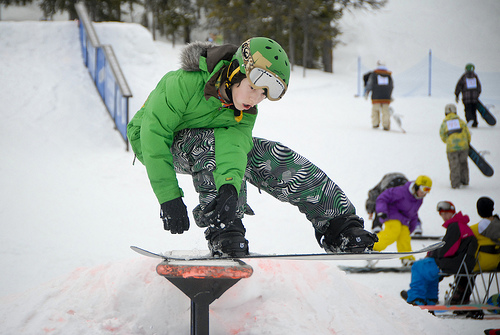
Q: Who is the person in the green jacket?
A: A young boy.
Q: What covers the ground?
A: Snow.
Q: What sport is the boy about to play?
A: Snowboarding.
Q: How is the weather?
A: Cold.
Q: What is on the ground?
A: Snow.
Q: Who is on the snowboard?
A: A boy.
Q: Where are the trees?
A: By the fence.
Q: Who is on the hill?
A: A bunch of kids.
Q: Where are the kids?
A: On the hill.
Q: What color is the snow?
A: White.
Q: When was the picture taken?
A: During the day.